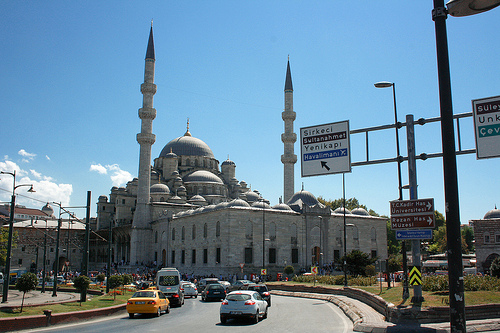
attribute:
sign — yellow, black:
[399, 257, 430, 291]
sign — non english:
[299, 122, 358, 189]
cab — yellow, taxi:
[125, 287, 170, 321]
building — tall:
[131, 27, 162, 199]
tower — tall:
[126, 12, 161, 276]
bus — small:
[155, 268, 187, 305]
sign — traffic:
[391, 197, 436, 214]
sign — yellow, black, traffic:
[405, 262, 424, 285]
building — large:
[93, 16, 389, 278]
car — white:
[218, 272, 284, 320]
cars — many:
[124, 264, 277, 326]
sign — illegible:
[392, 197, 435, 239]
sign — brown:
[393, 195, 444, 225]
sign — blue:
[389, 226, 434, 239]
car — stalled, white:
[218, 286, 269, 326]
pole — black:
[426, 2, 467, 331]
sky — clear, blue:
[2, 1, 494, 221]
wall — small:
[297, 118, 350, 178]